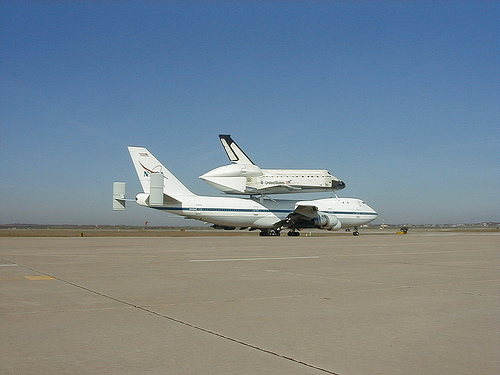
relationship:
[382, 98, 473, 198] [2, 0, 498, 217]
clouds in sky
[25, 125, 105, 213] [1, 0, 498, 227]
clouds in blue sky